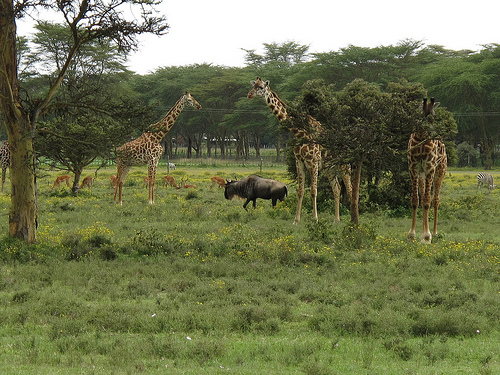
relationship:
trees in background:
[0, 17, 498, 162] [1, 20, 496, 172]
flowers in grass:
[1, 219, 497, 273] [3, 149, 498, 374]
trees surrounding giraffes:
[1, 0, 458, 249] [109, 76, 451, 246]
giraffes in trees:
[109, 76, 451, 246] [1, 0, 458, 249]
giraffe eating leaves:
[406, 97, 446, 246] [291, 75, 459, 187]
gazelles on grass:
[53, 172, 227, 192] [3, 149, 498, 374]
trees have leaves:
[1, 0, 458, 249] [291, 75, 459, 187]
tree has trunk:
[1, 0, 171, 241] [0, 0, 40, 247]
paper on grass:
[185, 334, 193, 343] [3, 149, 498, 374]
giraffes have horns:
[109, 76, 451, 246] [183, 74, 434, 108]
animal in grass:
[222, 173, 292, 213] [3, 149, 498, 374]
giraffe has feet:
[406, 97, 446, 246] [407, 227, 439, 245]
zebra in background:
[478, 172, 497, 189] [1, 20, 496, 172]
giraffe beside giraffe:
[406, 97, 446, 246] [247, 77, 360, 225]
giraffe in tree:
[406, 97, 446, 246] [277, 79, 460, 225]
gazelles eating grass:
[53, 172, 227, 192] [3, 149, 498, 374]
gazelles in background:
[53, 172, 227, 192] [1, 20, 496, 172]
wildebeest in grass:
[222, 173, 290, 211] [3, 149, 498, 374]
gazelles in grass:
[53, 172, 227, 192] [3, 149, 498, 374]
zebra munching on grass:
[478, 172, 497, 189] [3, 149, 498, 374]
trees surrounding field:
[1, 0, 458, 249] [3, 149, 498, 374]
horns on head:
[255, 75, 263, 83] [243, 77, 273, 105]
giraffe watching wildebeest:
[111, 89, 202, 206] [222, 173, 290, 211]